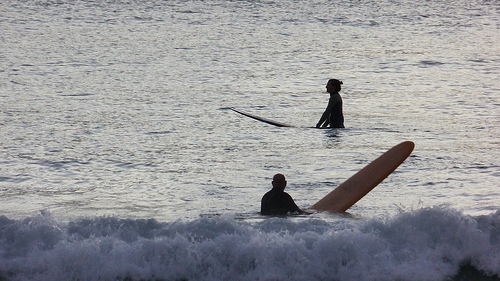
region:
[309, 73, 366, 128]
girl sitting on a surfboard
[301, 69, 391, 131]
girl in the water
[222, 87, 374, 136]
surfboard is in the water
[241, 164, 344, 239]
man sitting on a surfboard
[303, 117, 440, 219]
surfboard is out of the water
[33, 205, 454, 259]
waves in the water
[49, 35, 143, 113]
water is calm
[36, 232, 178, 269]
waves crashing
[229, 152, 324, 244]
man in the water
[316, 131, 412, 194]
surfboard is a orangish yellow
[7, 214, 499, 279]
spray of ocean waves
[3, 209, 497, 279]
ocean waves crashing to shore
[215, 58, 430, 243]
two people with surf boards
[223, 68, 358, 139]
person in water with surfboard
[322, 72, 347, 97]
profile with hair in bun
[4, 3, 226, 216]
ripples on open water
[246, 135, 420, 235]
man sitting on surfboard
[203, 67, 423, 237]
two people in the ocean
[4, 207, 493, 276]
white froth of ocean wave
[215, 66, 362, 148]
person standing in water with surfboard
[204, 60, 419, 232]
Two people in the image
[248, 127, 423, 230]
Person is holding a surfboard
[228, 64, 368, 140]
A woman in the background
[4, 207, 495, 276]
A wave of water in the foreground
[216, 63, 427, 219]
Two people are in shadow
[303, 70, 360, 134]
A side view of a person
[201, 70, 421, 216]
Two people in the water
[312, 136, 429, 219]
The surfboard is orange in color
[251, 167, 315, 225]
Man in the foreground is bald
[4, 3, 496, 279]
Photo was taken outdoors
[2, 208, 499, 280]
frothy wave moves to shore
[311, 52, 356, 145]
surfer waits for next wave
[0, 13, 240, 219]
ripples on the water surface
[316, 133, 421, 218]
a orange surf board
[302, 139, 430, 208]
a surf board raised up in the front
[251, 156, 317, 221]
surfer tirned toward the sea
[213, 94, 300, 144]
sky light is reflecting off the water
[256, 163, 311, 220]
surfer wearing a wet suit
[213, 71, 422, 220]
two surfers facing opposite directions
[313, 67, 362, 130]
hair stands up off the head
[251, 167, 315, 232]
man standing with half of his body in ocean water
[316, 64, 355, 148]
women standing with half her body in ocean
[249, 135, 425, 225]
man carrying his surfboard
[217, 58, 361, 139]
woman carrying her surfboard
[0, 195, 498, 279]
the waves of the ocean tide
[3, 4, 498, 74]
the vast ocean water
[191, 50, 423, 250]
a man and woman both are surfing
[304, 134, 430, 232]
a surfboard held by a man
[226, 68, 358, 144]
a surfboard held by a woman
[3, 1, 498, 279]
two person are surfing in a ocean